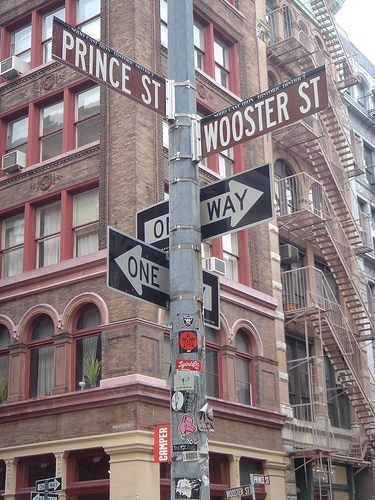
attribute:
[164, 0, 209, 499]
pole — big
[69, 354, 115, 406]
plant — green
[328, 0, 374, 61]
sky — white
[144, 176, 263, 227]
arrow — white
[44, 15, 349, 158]
signs — street signs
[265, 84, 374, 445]
steps — brown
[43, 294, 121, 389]
window — arched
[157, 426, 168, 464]
word — white, camper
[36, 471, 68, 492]
arrow — pointing right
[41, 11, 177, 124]
sign — brown, white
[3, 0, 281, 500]
building — brown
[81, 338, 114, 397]
plant — green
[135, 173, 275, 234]
arrow — pointing right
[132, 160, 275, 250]
sign — one way sign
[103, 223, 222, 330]
sign — one way sign